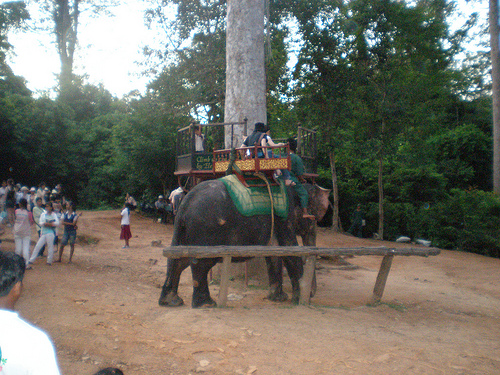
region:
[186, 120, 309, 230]
people riding an elephant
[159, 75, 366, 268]
people riding an elephant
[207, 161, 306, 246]
a green rug on the elephant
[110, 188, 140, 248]
Person standing in the dirt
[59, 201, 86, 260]
Person standing in the dirt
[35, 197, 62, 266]
Person standing in the dirt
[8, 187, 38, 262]
Person standing in the dirt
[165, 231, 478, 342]
Large wooden post in the ground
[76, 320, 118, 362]
Small patch of brown dirt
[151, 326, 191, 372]
Small patch of brown dirt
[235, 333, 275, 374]
Small patch of brown dirt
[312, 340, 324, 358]
Small patch of brown dirt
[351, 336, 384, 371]
Small patch of brown dirt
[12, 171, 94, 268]
the people are standing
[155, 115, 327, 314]
the people are riding the elephant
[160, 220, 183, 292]
the elephant has a tale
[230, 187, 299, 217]
the cushion is green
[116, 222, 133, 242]
the skirt is red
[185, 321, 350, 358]
the dirt is brown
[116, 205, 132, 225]
the shirt is white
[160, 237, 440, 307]
the post is brown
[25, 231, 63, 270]
the pants are white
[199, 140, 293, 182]
the basket is on top of the elephant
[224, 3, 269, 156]
The trunk is brown.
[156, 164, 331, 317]
The elephant is standing.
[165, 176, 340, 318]
The elephant is gray.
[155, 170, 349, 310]
The elephant has a green blanket.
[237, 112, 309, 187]
They are on the elephant.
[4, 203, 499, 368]
The ground is dirt.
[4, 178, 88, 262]
The people are standing.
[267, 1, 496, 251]
The trees are green.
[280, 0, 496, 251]
The trees are leafy.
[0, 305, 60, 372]
His shirt is white.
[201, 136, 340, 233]
the elephant's saddle pad is green & beige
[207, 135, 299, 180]
the "saddle" is more like a box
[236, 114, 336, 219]
it appears there are 3 people riding him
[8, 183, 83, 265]
many people are looking on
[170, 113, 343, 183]
it appears to be a deck around the tree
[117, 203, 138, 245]
this girl is wearing a red skirt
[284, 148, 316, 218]
this person is dressed all in green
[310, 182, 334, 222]
the elephant has pink on the edge of his ear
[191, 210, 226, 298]
he also has pink areas on his body & hind leg